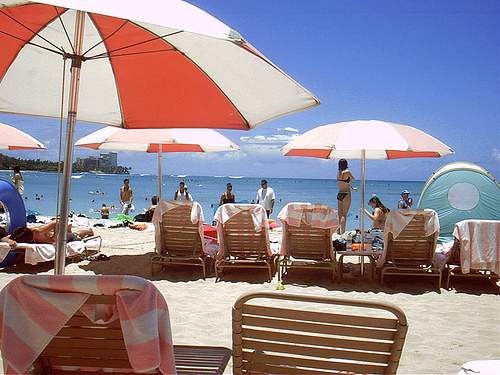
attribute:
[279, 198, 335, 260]
towels — pink, white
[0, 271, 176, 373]
towels — pink, white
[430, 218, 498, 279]
towels — pink, white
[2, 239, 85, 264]
towels — pink, white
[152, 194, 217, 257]
towels — pink, white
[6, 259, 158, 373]
towel — white, pink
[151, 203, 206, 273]
chair — tan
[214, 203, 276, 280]
chair — tan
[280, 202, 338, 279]
chair — tan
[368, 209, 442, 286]
chair — tan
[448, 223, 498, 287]
chair — tan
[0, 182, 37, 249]
tube — large, blue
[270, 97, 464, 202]
umbrella — white, red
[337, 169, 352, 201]
bikini — black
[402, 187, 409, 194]
baseball cap — blue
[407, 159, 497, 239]
beach tent — blue, white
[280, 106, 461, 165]
umbrella — red, white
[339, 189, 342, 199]
bikini — black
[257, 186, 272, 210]
shirt — white